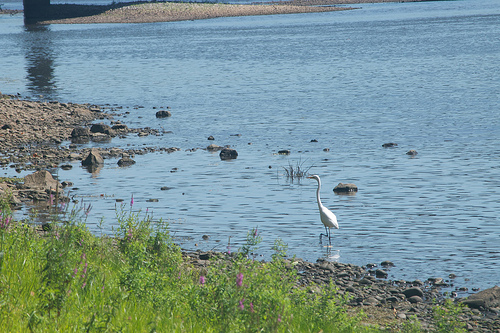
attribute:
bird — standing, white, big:
[283, 157, 358, 272]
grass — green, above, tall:
[51, 225, 211, 306]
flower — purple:
[202, 245, 256, 303]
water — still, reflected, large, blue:
[206, 36, 415, 172]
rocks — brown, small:
[54, 91, 139, 164]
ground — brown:
[100, 2, 257, 31]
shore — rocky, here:
[321, 260, 434, 311]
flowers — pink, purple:
[170, 213, 264, 293]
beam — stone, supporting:
[29, 3, 62, 31]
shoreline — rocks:
[12, 73, 274, 233]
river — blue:
[75, 35, 430, 110]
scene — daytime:
[10, 10, 498, 304]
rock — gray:
[375, 266, 419, 301]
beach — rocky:
[31, 76, 190, 200]